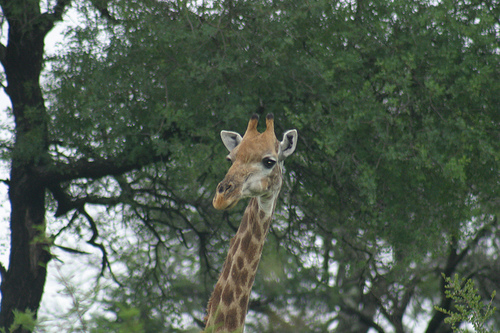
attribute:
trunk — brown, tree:
[0, 182, 80, 302]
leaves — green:
[427, 257, 498, 331]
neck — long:
[204, 199, 281, 331]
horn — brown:
[265, 110, 273, 133]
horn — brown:
[242, 105, 258, 134]